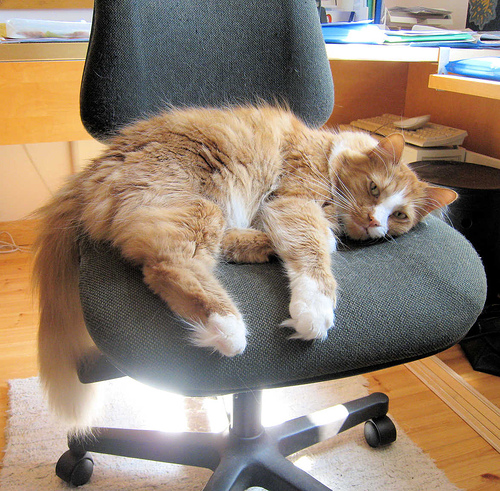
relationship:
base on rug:
[53, 389, 395, 489] [6, 362, 450, 489]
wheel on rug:
[364, 416, 399, 446] [6, 362, 450, 489]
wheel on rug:
[55, 449, 93, 485] [6, 362, 450, 489]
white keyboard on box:
[355, 107, 473, 149] [354, 125, 464, 228]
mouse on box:
[352, 105, 470, 148] [354, 125, 464, 228]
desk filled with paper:
[319, 9, 498, 204] [334, 11, 385, 59]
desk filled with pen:
[319, 9, 498, 204] [345, 3, 363, 27]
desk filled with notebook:
[319, 9, 498, 204] [364, 15, 483, 65]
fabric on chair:
[98, 19, 330, 134] [102, 244, 497, 369]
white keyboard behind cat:
[355, 107, 473, 149] [20, 85, 457, 359]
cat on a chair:
[170, 98, 413, 330] [71, 15, 410, 365]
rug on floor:
[6, 362, 450, 489] [46, 385, 426, 461]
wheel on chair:
[364, 416, 399, 446] [53, 0, 488, 490]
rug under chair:
[6, 362, 450, 489] [53, 0, 488, 490]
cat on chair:
[23, 98, 462, 358] [53, 0, 488, 490]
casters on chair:
[363, 409, 408, 446] [53, 0, 488, 490]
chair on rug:
[53, 0, 488, 490] [341, 432, 390, 487]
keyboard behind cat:
[350, 108, 468, 148] [50, 75, 490, 386]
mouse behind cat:
[352, 105, 470, 148] [50, 75, 490, 386]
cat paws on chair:
[285, 272, 340, 344] [53, 0, 488, 490]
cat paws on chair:
[182, 301, 249, 362] [53, 0, 488, 490]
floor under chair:
[0, 236, 500, 489] [53, 0, 488, 490]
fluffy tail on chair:
[31, 197, 94, 458] [59, 7, 316, 429]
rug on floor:
[6, 362, 450, 489] [0, 236, 500, 489]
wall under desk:
[2, 62, 86, 147] [5, 25, 490, 93]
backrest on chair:
[85, 13, 365, 125] [67, 7, 498, 392]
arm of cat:
[263, 173, 340, 350] [23, 98, 462, 358]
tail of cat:
[26, 168, 112, 459] [27, 98, 468, 436]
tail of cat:
[26, 168, 112, 459] [36, 77, 481, 355]